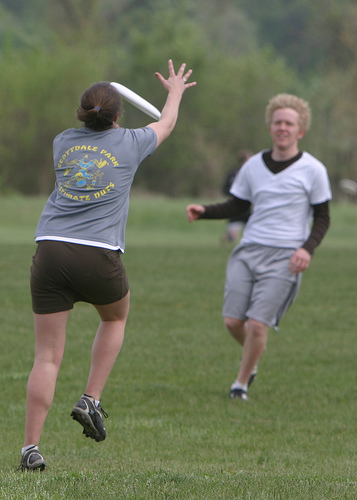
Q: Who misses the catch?
A: The running woman.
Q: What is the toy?
A: A Frisbee.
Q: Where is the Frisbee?
A: In the air.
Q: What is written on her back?
A: Scottdale Park.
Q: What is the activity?
A: Playing Frisbee.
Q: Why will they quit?
A: It gets dark or they tire.